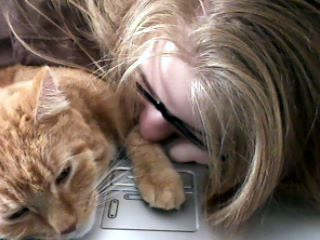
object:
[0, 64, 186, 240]
cat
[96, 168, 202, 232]
device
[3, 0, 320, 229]
blonde hair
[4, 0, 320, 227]
lady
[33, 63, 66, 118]
ear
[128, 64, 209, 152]
glasses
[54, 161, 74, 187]
eyes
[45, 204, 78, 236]
nose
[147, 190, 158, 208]
paw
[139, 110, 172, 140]
nose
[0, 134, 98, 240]
face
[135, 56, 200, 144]
face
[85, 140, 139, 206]
whiskers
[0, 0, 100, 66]
brown jacket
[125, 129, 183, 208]
leg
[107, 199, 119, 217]
button